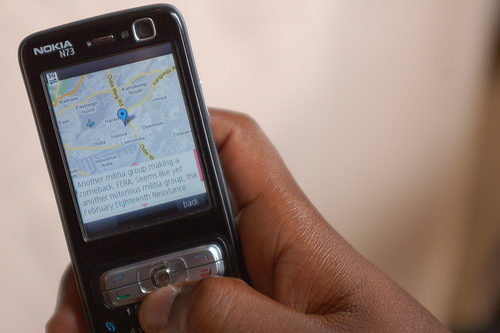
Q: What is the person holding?
A: Phone.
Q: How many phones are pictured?
A: 1.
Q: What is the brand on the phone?
A: Nokia.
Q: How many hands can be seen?
A: 1.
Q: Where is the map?
A: Screen.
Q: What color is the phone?
A: Black.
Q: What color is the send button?
A: Green.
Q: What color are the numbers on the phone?
A: White.